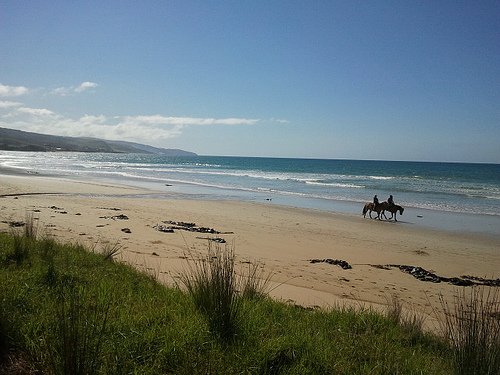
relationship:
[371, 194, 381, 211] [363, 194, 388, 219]
person riding horse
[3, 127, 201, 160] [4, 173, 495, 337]
hill behind beach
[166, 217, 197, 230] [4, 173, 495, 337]
rock on beach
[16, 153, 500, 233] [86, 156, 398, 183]
ocean has waves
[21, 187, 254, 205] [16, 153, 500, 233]
stream leading to ocean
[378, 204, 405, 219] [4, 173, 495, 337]
horse on beach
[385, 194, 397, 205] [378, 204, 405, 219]
person riding horse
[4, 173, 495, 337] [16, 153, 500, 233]
beach by ocean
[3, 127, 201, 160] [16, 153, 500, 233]
hill by ocean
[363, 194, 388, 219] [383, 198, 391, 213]
horse has head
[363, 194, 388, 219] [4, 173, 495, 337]
horse walking on beach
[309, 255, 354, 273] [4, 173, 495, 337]
seaweed on beach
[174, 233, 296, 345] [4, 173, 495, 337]
grass next to beach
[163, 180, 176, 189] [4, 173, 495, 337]
debris washed up on beach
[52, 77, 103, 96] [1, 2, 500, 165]
cloud in sky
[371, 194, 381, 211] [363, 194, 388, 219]
person on horse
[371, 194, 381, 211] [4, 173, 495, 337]
person by beach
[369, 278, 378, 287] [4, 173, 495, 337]
footprint in beach